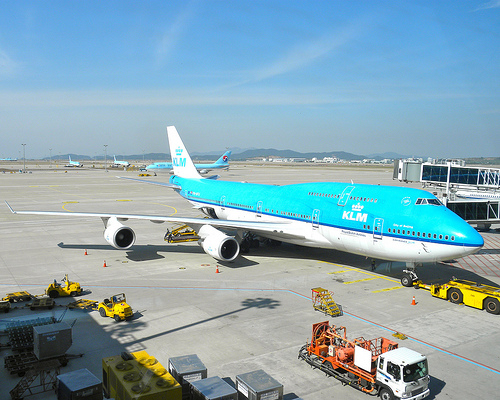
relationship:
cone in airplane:
[212, 263, 222, 273] [2, 125, 483, 288]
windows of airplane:
[412, 192, 446, 207] [0, 120, 490, 282]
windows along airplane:
[354, 212, 462, 254] [2, 125, 483, 288]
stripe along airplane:
[184, 196, 486, 250] [0, 120, 490, 282]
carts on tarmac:
[415, 276, 499, 315] [18, 157, 498, 389]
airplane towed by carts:
[2, 125, 483, 288] [428, 275, 500, 316]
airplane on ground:
[2, 125, 483, 288] [175, 285, 232, 336]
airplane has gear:
[2, 125, 483, 288] [401, 273, 413, 286]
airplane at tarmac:
[2, 125, 483, 288] [18, 157, 498, 389]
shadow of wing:
[55, 237, 218, 266] [3, 193, 266, 231]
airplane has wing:
[0, 120, 490, 282] [3, 193, 266, 231]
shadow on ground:
[117, 302, 268, 353] [142, 275, 202, 308]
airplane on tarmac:
[2, 125, 483, 288] [18, 157, 498, 389]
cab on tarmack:
[296, 321, 435, 400] [3, 161, 498, 398]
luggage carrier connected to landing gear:
[410, 275, 500, 316] [400, 262, 417, 284]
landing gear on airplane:
[400, 262, 417, 284] [2, 125, 483, 288]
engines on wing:
[99, 216, 244, 264] [2, 200, 272, 229]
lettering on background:
[335, 205, 372, 225] [134, 141, 493, 261]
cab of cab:
[375, 346, 433, 398] [296, 321, 435, 400]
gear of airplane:
[401, 273, 413, 286] [0, 120, 490, 282]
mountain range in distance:
[39, 146, 386, 161] [34, 123, 497, 185]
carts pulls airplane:
[428, 275, 500, 316] [2, 125, 483, 288]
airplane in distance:
[144, 150, 232, 175] [6, 104, 499, 201]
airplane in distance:
[2, 125, 483, 288] [6, 104, 499, 201]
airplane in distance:
[64, 154, 84, 168] [6, 104, 499, 201]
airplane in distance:
[111, 155, 131, 171] [6, 104, 499, 201]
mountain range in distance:
[39, 146, 428, 161] [12, 127, 495, 184]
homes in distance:
[246, 156, 463, 166] [12, 127, 495, 184]